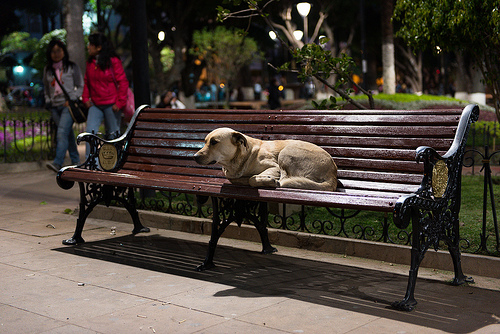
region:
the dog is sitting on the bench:
[194, 130, 425, 237]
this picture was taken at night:
[13, 5, 498, 306]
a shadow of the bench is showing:
[32, 217, 472, 329]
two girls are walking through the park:
[14, 29, 134, 201]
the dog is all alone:
[145, 105, 445, 260]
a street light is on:
[257, 2, 399, 66]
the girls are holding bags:
[21, 42, 176, 167]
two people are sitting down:
[144, 86, 229, 133]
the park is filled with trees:
[1, 0, 486, 78]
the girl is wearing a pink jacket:
[73, 34, 176, 132]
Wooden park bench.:
[58, 89, 490, 309]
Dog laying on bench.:
[176, 114, 365, 223]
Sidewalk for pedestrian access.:
[0, 37, 115, 329]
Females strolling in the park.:
[30, 20, 152, 185]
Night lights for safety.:
[258, 1, 350, 88]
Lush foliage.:
[375, 0, 499, 148]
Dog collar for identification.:
[220, 125, 262, 187]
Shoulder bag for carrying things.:
[51, 72, 98, 132]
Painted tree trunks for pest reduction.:
[372, 33, 412, 107]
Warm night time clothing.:
[35, 61, 139, 113]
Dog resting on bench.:
[192, 122, 339, 190]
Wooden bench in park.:
[52, 96, 477, 312]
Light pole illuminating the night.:
[294, 2, 312, 47]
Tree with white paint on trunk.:
[375, 1, 470, 92]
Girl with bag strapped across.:
[42, 37, 84, 176]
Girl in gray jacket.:
[38, 37, 85, 171]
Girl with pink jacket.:
[85, 34, 132, 164]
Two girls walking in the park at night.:
[42, 34, 134, 174]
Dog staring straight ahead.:
[192, 127, 336, 191]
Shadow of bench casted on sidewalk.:
[50, 227, 499, 332]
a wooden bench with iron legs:
[50, 101, 480, 311]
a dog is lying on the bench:
[188, 124, 345, 194]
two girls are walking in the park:
[38, 29, 132, 212]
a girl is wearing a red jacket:
[80, 57, 127, 113]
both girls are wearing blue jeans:
[46, 102, 122, 186]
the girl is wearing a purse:
[43, 60, 86, 123]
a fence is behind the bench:
[4, 109, 499, 254]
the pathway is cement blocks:
[4, 166, 499, 332]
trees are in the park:
[2, 0, 497, 95]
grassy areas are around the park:
[12, 132, 499, 259]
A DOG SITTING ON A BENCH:
[51, 96, 491, 319]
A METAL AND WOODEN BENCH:
[51, 94, 492, 275]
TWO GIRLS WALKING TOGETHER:
[29, 24, 146, 188]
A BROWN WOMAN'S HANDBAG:
[53, 70, 95, 125]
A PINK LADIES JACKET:
[79, 54, 139, 116]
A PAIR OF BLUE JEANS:
[36, 106, 83, 174]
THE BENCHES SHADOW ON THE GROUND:
[74, 229, 488, 329]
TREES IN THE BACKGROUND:
[379, 1, 498, 96]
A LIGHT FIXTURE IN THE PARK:
[259, 4, 330, 62]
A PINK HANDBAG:
[122, 79, 141, 121]